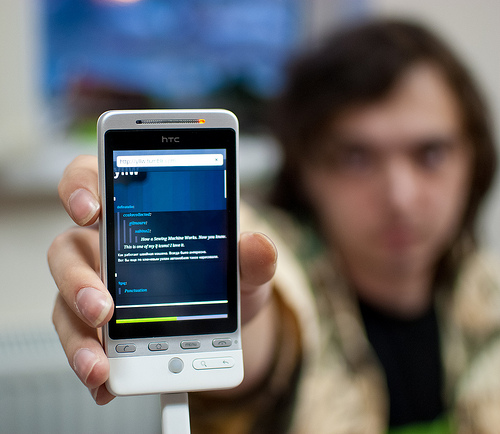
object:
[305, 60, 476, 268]
face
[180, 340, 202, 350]
power button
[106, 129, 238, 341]
screen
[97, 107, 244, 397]
cell phone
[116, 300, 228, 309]
row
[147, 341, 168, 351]
buttons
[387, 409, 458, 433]
stripe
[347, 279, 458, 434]
shirt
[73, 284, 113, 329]
finger nail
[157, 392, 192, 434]
charging plug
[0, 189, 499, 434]
foreground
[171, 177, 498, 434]
coat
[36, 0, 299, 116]
screen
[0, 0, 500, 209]
background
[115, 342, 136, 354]
call button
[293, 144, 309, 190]
ear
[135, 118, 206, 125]
microphone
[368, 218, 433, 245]
mouth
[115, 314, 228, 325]
download progress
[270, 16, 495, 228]
hair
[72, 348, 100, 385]
nails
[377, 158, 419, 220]
nose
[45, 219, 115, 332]
fingers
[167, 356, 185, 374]
home button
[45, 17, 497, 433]
man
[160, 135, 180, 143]
logo